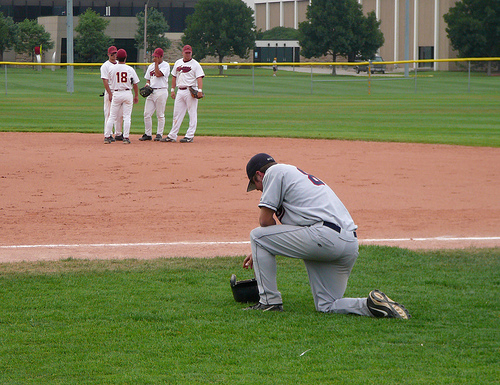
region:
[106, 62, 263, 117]
the jersey is white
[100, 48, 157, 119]
the jersey is white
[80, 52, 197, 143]
the jersey is white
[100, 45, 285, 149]
the jersey is white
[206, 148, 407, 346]
baseball player kneeling on the ground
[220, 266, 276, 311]
base ball glove on grass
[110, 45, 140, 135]
baseball player wearing white uniform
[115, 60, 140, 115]
uniform with number eightteen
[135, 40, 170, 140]
base ball player wearing a white uiform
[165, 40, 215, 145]
baseball player wearing a white uniform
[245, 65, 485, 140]
green grass in a baseball field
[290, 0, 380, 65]
green tree in base ball field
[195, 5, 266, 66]
green tree in a baseball field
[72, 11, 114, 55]
green tree in baseball field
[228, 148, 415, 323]
the man is kneeling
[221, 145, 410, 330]
man is wearing a gray uniform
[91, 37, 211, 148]
a group of players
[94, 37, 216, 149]
players wearing white uniforms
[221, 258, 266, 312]
a black helmet on the ground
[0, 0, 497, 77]
the buildings are brown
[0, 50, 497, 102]
fence with yellow padding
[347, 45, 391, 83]
a gray van is parked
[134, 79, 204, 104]
two black gloves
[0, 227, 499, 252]
a white line on baseball field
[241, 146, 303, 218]
Person wearing hat on head.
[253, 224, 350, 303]
Person wearing gray pants.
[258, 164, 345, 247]
Person wearing gray shirt.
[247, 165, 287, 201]
Person has brown hair.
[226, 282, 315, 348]
Person wearing black and white shoes.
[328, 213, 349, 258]
Person wearing dark belt.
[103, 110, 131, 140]
Person wearing white pants.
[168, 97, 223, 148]
Person wearing white pants.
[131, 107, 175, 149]
Person wearing white pants.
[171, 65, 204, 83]
Person wearing white shirt.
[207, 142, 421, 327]
Baseball player kneeling on the ground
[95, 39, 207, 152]
Group of baseball players standing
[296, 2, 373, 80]
Green and brown tree in background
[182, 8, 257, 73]
Green and brown tree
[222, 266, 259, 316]
Baseball player's mitt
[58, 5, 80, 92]
Silver metal pole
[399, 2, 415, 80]
Tall silver pole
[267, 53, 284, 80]
Person in the background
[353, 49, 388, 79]
Car in the background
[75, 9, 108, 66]
Green tree in the background